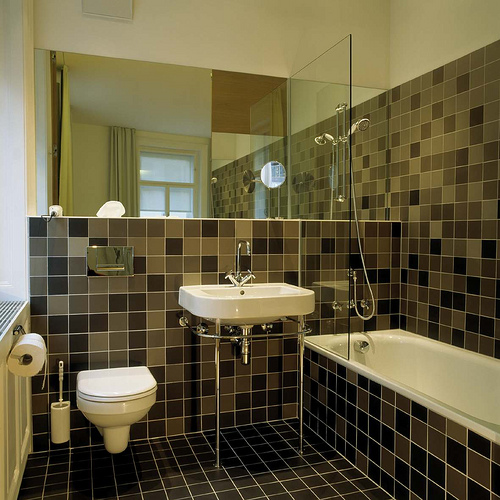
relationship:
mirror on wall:
[48, 48, 288, 224] [388, 0, 498, 330]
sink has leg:
[176, 281, 316, 326] [211, 318, 222, 470]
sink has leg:
[176, 281, 316, 326] [291, 313, 307, 460]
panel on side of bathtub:
[292, 37, 348, 380] [305, 318, 485, 461]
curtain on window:
[108, 125, 136, 217] [136, 140, 199, 220]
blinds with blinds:
[140, 150, 196, 217] [140, 150, 196, 210]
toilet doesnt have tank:
[79, 366, 155, 450] [82, 305, 162, 367]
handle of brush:
[52, 358, 64, 399] [48, 359, 73, 445]